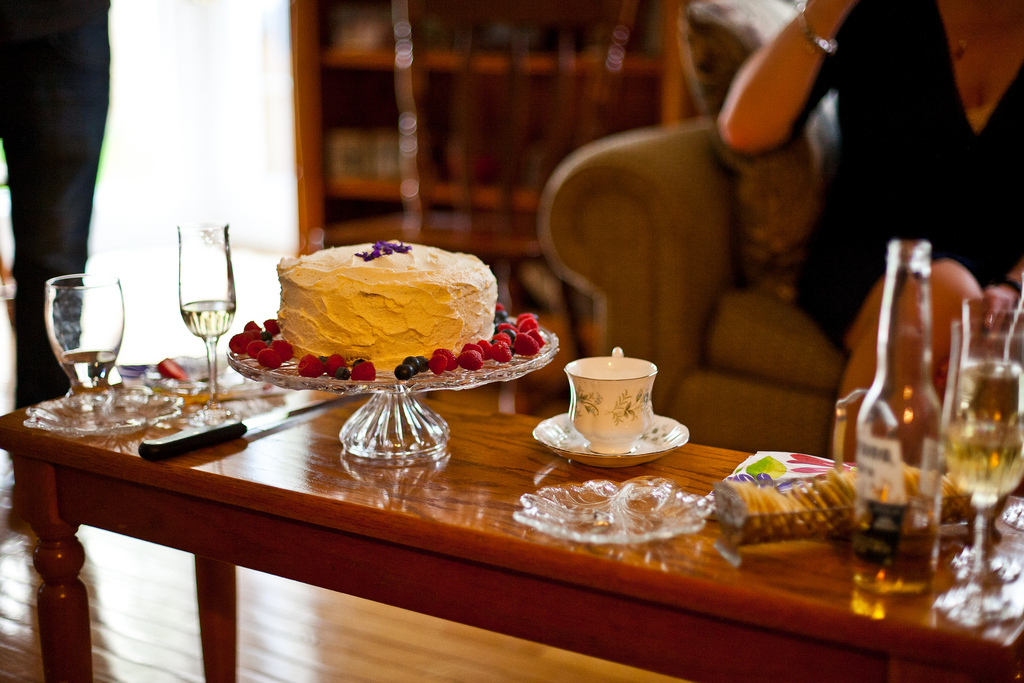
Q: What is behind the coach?
A: A wooden chair.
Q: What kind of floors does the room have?
A: Wooden.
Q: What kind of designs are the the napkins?
A: Colorful.